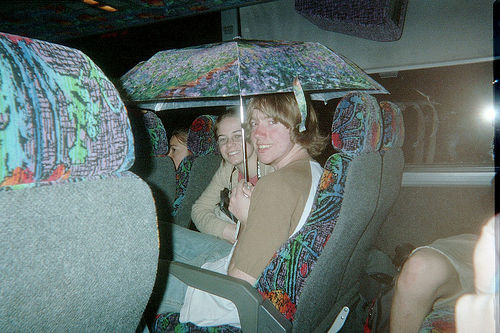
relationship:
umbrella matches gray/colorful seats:
[125, 35, 390, 105] [253, 93, 407, 333]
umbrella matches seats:
[125, 35, 390, 105] [136, 103, 217, 218]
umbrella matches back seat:
[125, 35, 390, 105] [0, 29, 158, 332]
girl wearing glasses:
[188, 109, 270, 245] [213, 130, 245, 146]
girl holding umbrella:
[188, 109, 270, 245] [113, 35, 389, 109]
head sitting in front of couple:
[160, 120, 197, 174] [207, 90, 323, 304]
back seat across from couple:
[0, 29, 124, 329] [183, 80, 325, 309]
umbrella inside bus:
[113, 35, 389, 109] [3, 2, 497, 327]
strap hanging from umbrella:
[291, 75, 308, 135] [114, 33, 389, 110]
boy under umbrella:
[153, 92, 329, 319] [116, 35, 391, 183]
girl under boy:
[190, 109, 272, 242] [153, 92, 329, 319]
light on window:
[466, 97, 498, 129] [381, 71, 483, 166]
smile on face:
[251, 140, 281, 156] [248, 90, 305, 170]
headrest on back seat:
[0, 32, 147, 187] [0, 29, 158, 332]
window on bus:
[360, 55, 495, 185] [366, 53, 497, 188]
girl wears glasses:
[190, 109, 272, 242] [221, 132, 253, 149]